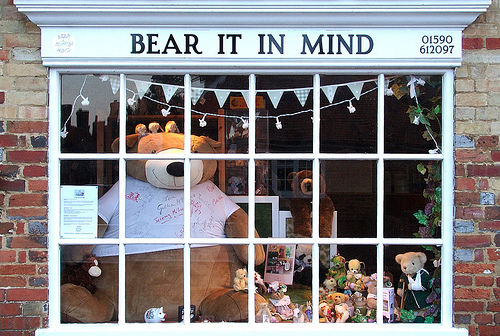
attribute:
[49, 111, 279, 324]
bear — large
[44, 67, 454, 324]
frame — white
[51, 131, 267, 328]
bear — little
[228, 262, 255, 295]
bear — big